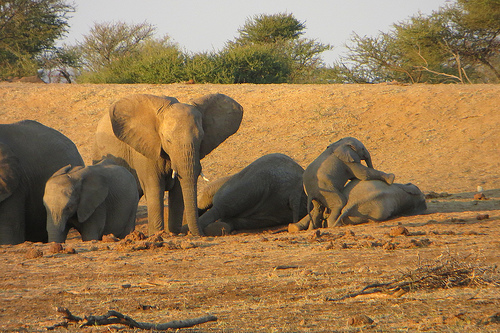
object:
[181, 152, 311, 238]
elephant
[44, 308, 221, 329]
branch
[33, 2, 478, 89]
sky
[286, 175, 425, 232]
elephant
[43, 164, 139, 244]
baby elephant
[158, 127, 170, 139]
eyes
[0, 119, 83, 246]
elephant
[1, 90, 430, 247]
herd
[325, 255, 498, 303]
branches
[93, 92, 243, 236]
big elephant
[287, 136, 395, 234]
baby elephant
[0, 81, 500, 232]
hill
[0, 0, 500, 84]
leaves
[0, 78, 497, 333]
dirt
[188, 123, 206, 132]
eyes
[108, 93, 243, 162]
ears